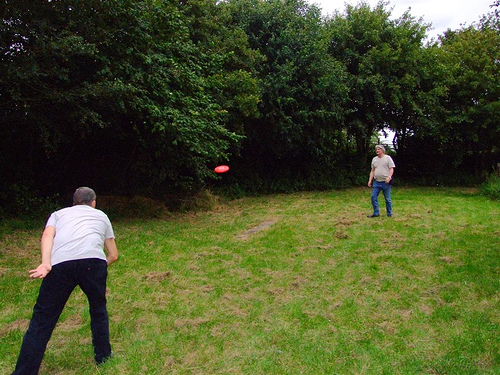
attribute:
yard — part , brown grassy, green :
[4, 174, 499, 373]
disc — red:
[212, 161, 231, 176]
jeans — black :
[12, 261, 137, 366]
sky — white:
[299, 1, 498, 51]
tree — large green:
[318, 0, 427, 182]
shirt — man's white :
[47, 203, 118, 270]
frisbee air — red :
[207, 147, 235, 182]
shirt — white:
[32, 200, 139, 277]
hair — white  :
[372, 142, 386, 149]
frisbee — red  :
[212, 161, 232, 175]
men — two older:
[13, 67, 441, 374]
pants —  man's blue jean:
[14, 261, 111, 374]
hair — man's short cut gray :
[62, 183, 102, 200]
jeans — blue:
[359, 176, 416, 210]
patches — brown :
[28, 198, 478, 350]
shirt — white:
[36, 201, 118, 271]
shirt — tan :
[364, 151, 399, 186]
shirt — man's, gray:
[370, 156, 395, 178]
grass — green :
[2, 227, 499, 368]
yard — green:
[6, 190, 499, 368]